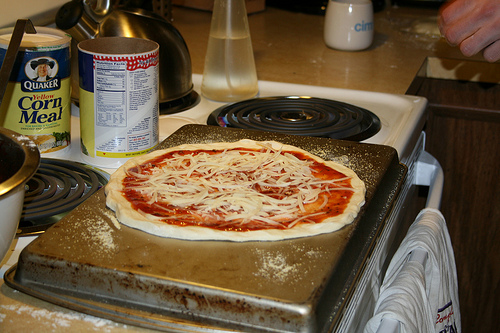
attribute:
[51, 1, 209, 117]
kettle — tea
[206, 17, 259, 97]
bottle — clear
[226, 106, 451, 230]
surface — burnt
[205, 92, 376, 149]
burner — black, stove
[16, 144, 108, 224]
burner — black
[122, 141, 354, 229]
cheese — shredded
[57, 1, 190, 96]
kettle — silver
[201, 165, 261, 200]
cheese — shredded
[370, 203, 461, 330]
towel — dish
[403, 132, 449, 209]
handle — oven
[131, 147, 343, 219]
cheese — unmelted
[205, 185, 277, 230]
tomato sauce — red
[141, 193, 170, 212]
sauce — red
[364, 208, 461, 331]
shirt — white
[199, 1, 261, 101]
bottle — stove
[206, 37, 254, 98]
liquid — clear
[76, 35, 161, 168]
container — small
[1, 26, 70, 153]
container — small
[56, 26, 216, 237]
container — small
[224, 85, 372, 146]
burner — on right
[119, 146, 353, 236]
sauce — red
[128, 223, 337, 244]
crust — pizza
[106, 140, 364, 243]
pizza — small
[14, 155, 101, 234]
burner — black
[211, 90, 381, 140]
burner — black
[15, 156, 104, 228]
burner — black